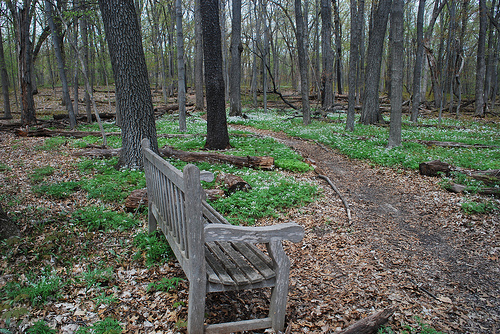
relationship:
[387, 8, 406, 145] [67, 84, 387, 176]
tree covering fence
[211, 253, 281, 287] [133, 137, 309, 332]
slat on bench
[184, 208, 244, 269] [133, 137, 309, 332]
slat on bench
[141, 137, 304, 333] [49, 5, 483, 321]
bench in middle of forest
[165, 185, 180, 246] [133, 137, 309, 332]
wooden slat on bench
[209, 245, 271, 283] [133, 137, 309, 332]
wooden slat on bench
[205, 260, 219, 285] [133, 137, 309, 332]
slat on bench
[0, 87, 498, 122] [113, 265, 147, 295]
fence with leaves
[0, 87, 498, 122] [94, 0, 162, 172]
fence by tree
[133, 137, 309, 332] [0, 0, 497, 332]
bench in forest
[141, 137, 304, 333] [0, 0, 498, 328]
bench in forrest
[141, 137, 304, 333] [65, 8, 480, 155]
bench in forrest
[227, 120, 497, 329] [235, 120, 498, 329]
trail made out of dirt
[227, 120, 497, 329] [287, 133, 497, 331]
trail made out of leaves